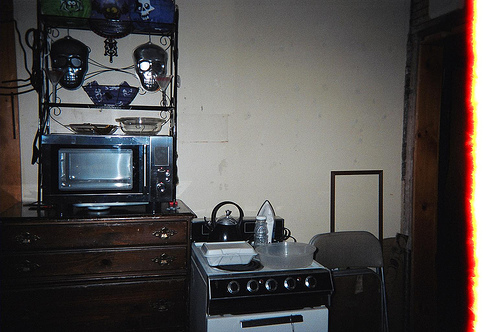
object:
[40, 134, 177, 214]
microwave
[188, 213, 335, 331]
oven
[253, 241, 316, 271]
container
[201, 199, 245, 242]
tea pot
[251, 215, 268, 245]
bottle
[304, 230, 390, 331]
chair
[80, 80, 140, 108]
bowl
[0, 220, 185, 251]
drawer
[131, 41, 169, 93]
skull pan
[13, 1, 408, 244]
wall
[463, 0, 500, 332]
burn line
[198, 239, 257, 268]
takeout box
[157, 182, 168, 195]
knob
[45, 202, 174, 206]
shelf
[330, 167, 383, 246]
frame